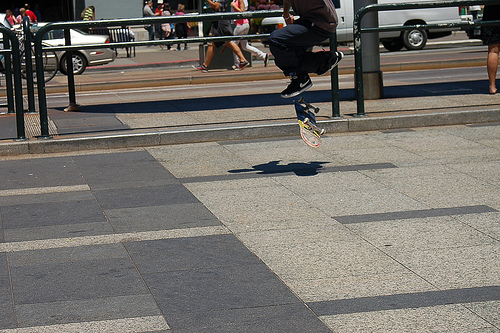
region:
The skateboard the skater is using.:
[295, 97, 325, 149]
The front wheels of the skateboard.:
[303, 119, 325, 134]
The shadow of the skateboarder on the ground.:
[225, 150, 325, 178]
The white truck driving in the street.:
[257, 2, 462, 49]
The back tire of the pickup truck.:
[404, 26, 429, 49]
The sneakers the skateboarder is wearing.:
[276, 52, 343, 101]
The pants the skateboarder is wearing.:
[271, 22, 328, 76]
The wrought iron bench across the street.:
[64, 19, 138, 54]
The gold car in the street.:
[15, 20, 116, 73]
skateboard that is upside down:
[292, 96, 327, 149]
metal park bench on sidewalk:
[84, 25, 136, 59]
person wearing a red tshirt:
[21, 0, 37, 25]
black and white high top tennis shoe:
[281, 73, 315, 98]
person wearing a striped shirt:
[82, 3, 97, 26]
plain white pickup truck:
[261, 1, 475, 51]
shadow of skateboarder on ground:
[227, 153, 333, 180]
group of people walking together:
[140, 0, 195, 52]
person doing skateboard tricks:
[268, 3, 345, 98]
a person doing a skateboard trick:
[256, 0, 356, 102]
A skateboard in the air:
[286, 90, 321, 150]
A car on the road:
[0, 20, 120, 75]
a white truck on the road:
[260, 0, 465, 55]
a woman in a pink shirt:
[230, 0, 270, 74]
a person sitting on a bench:
[111, 22, 135, 55]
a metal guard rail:
[33, 8, 343, 137]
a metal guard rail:
[1, 21, 30, 139]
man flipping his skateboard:
[264, 0, 343, 151]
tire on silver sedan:
[2, 18, 116, 78]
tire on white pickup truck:
[259, 0, 461, 57]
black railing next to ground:
[1, 0, 498, 332]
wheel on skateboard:
[292, 96, 326, 148]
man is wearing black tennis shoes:
[269, 1, 344, 101]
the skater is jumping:
[258, 1, 360, 158]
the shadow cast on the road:
[223, 153, 332, 183]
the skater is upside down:
[288, 89, 330, 152]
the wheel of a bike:
[15, 38, 65, 89]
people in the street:
[137, 3, 274, 78]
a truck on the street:
[263, 1, 466, 48]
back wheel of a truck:
[398, 16, 432, 54]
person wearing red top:
[20, 1, 40, 23]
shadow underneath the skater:
[235, 150, 327, 183]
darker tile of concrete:
[96, 187, 186, 206]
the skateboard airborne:
[296, 97, 328, 150]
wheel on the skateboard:
[306, 112, 310, 125]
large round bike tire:
[23, 39, 55, 79]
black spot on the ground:
[384, 242, 394, 249]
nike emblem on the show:
[296, 79, 313, 86]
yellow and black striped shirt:
[82, 8, 93, 18]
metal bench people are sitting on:
[107, 27, 129, 40]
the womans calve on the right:
[486, 49, 498, 73]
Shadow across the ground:
[221, 152, 336, 184]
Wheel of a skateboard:
[318, 124, 328, 138]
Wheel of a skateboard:
[313, 103, 321, 111]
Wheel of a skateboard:
[301, 115, 311, 125]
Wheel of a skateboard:
[297, 95, 305, 102]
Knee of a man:
[263, 24, 292, 53]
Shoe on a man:
[278, 70, 313, 98]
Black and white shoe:
[277, 75, 315, 100]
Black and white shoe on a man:
[278, 71, 313, 99]